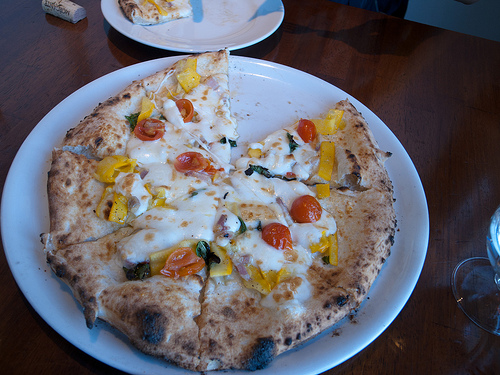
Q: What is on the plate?
A: Pizza.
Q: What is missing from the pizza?
A: One slice.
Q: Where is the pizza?
A: White plate.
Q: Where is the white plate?
A: Wooden table.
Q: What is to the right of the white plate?
A: Wine glass.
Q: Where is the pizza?
A: On plate.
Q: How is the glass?
A: Steamed.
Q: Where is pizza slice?
A: On plate.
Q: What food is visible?
A: Pizza.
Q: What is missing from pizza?
A: Slice.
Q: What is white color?
A: Plate.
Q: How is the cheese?
A: Melted.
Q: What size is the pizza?
A: Small.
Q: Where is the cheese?
A: On pizza.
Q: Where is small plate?
A: In background.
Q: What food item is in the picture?
A: A pizza.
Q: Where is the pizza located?
A: On a plate.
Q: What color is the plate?
A: White.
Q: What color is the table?
A: Brown.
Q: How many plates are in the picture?
A: Two.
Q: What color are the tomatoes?
A: Red.